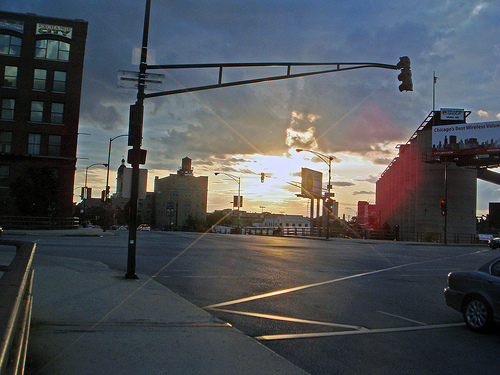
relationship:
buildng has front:
[22, 19, 73, 211] [9, 92, 100, 205]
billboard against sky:
[285, 149, 332, 201] [188, 20, 398, 200]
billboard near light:
[285, 149, 332, 201] [334, 26, 447, 95]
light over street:
[334, 26, 447, 95] [194, 224, 413, 359]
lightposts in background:
[171, 159, 407, 262] [160, 120, 476, 375]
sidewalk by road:
[29, 239, 203, 374] [194, 224, 413, 359]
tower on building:
[171, 149, 198, 183] [164, 162, 282, 245]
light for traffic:
[334, 26, 447, 95] [403, 192, 497, 373]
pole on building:
[420, 69, 454, 114] [164, 162, 282, 245]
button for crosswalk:
[111, 212, 149, 262] [194, 224, 413, 359]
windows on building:
[19, 52, 66, 161] [164, 162, 282, 245]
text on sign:
[433, 117, 485, 137] [402, 61, 493, 177]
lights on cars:
[135, 218, 154, 235] [95, 202, 134, 250]